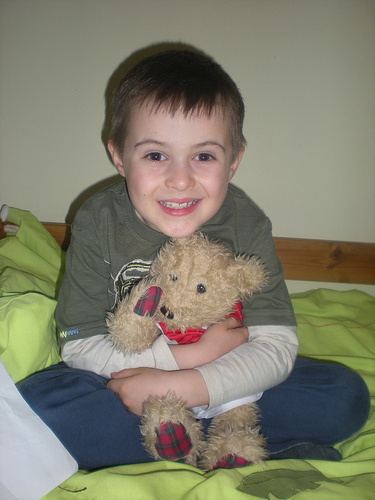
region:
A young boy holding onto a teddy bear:
[54, 35, 291, 353]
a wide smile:
[129, 191, 228, 238]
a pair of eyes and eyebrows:
[132, 136, 232, 171]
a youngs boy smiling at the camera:
[93, 33, 258, 238]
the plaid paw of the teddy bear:
[131, 274, 173, 325]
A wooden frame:
[295, 222, 373, 298]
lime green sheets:
[325, 295, 374, 356]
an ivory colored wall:
[293, 71, 370, 213]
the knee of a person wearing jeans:
[314, 347, 374, 453]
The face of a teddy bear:
[147, 237, 261, 331]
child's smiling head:
[94, 62, 247, 238]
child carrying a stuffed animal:
[135, 248, 283, 461]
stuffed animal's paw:
[114, 281, 179, 330]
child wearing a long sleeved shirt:
[78, 180, 311, 419]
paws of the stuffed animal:
[137, 401, 271, 474]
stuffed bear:
[139, 240, 274, 462]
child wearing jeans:
[35, 368, 374, 475]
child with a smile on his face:
[128, 131, 256, 239]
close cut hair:
[102, 51, 273, 159]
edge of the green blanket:
[2, 206, 70, 369]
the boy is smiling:
[110, 109, 240, 275]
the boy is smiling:
[187, 176, 270, 320]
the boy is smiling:
[106, 123, 269, 365]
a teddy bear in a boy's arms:
[109, 242, 272, 471]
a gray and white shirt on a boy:
[53, 182, 302, 396]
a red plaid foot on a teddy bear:
[156, 418, 196, 456]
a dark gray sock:
[275, 443, 344, 458]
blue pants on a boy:
[20, 352, 367, 458]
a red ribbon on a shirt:
[156, 301, 246, 345]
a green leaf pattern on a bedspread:
[224, 459, 346, 496]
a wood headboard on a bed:
[39, 217, 372, 284]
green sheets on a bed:
[3, 210, 374, 495]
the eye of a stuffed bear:
[192, 282, 206, 291]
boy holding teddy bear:
[53, 48, 295, 423]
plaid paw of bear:
[149, 411, 189, 466]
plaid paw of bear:
[207, 435, 257, 473]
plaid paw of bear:
[135, 279, 159, 319]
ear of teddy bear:
[225, 263, 260, 297]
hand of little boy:
[110, 365, 185, 403]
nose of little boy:
[159, 172, 195, 192]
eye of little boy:
[132, 143, 168, 170]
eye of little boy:
[189, 150, 220, 173]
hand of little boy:
[213, 320, 248, 360]